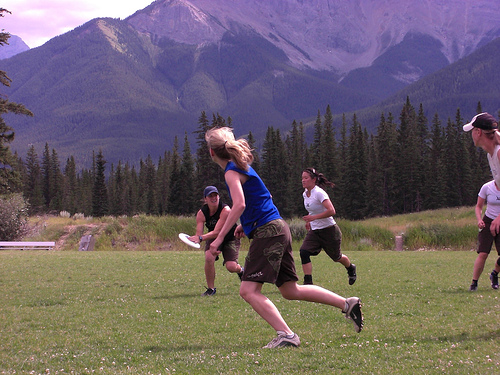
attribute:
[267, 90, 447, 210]
tree — evergreen, tall, covered, pine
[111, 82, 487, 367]
women — playing, running, wearing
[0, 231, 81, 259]
bench — metal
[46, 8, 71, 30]
sky — hazy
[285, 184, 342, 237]
top — white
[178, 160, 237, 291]
woman — catching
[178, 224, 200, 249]
frisbett — white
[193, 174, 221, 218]
cap — blue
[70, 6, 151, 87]
mountain — tall, range, large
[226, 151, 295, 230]
shirt — blue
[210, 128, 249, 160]
hair — blond, dark, blonde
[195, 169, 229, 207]
hat — black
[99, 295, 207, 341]
grass — green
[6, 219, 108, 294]
celte — white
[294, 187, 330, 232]
shirt — white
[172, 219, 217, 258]
frisbee — white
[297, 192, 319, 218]
nike — brand